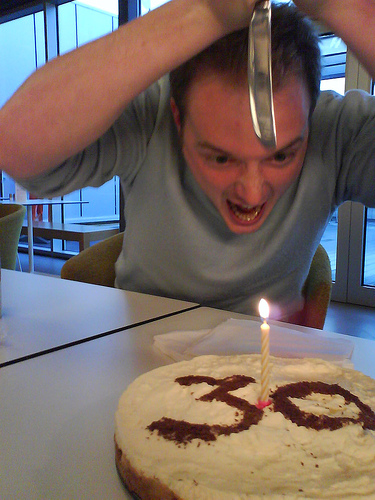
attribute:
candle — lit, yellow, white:
[241, 294, 283, 400]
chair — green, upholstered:
[59, 228, 332, 329]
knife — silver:
[245, 11, 286, 153]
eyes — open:
[203, 147, 295, 171]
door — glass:
[316, 31, 374, 308]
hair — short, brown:
[168, 3, 321, 132]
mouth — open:
[223, 197, 270, 227]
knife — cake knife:
[228, 7, 298, 132]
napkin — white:
[154, 316, 355, 367]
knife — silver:
[242, 0, 280, 154]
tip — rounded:
[255, 130, 279, 150]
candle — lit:
[253, 297, 273, 409]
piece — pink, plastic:
[255, 399, 273, 407]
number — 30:
[146, 366, 363, 454]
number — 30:
[147, 370, 374, 447]